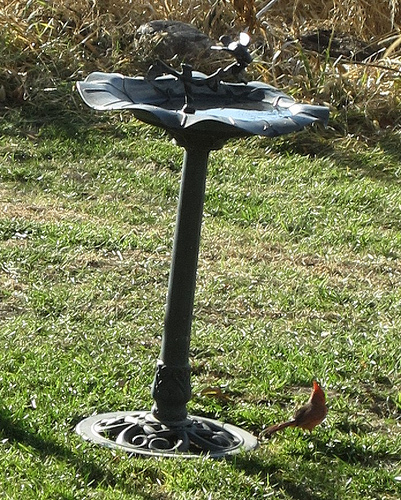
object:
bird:
[259, 378, 328, 438]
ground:
[238, 270, 356, 319]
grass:
[42, 140, 116, 163]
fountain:
[155, 95, 218, 122]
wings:
[297, 414, 319, 427]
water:
[188, 96, 237, 111]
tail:
[255, 416, 297, 435]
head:
[309, 378, 326, 403]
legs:
[308, 426, 314, 440]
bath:
[76, 30, 329, 135]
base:
[73, 410, 257, 458]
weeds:
[277, 45, 312, 67]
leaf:
[208, 386, 232, 401]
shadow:
[277, 143, 319, 170]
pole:
[150, 146, 208, 413]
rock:
[308, 29, 359, 60]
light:
[228, 20, 253, 53]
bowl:
[160, 72, 227, 127]